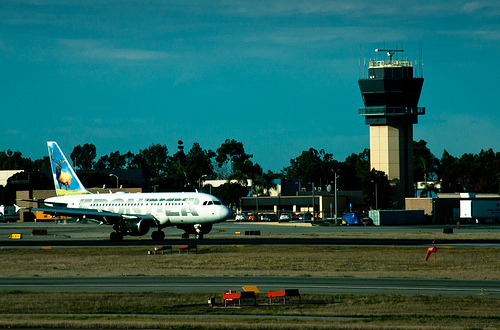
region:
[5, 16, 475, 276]
airport with an airplane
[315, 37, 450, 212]
airplane tower is overhead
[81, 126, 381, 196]
tree line is green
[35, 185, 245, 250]
landing gear is down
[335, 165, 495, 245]
airport tower base in background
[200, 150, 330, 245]
runway buildings behind the scene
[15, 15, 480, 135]
cloudless sky in the background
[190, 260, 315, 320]
runway objects on the ground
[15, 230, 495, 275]
grassy ground beneath the plane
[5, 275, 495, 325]
grassy area for airport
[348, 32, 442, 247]
air traffic controller tower at airport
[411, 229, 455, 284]
orange reflective wind sock at airport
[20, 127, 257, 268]
large jetliner at airport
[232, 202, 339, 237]
cars parked in parking lot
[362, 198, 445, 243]
storage building at airport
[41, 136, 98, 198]
elk painted on tail wing of airport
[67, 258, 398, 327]
asphalt runway at airport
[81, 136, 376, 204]
trees with green leaves at a distanse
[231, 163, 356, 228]
building on airport property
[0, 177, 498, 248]
airplane going down run way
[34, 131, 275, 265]
white plane with design on tail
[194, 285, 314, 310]
several colored tables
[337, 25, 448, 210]
large air traffic control tower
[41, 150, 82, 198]
blue and yellow on airplane tail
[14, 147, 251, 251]
airplane on tar mac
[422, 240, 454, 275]
something red in median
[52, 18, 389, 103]
light whispy clouds in sky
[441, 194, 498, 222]
white box truck in photograph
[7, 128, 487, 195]
row of trees in photograph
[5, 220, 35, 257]
something yellow on runway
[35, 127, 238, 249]
Passenger plane on the runway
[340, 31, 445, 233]
Airport control tower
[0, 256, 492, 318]
Empty runway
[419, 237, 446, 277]
Small orange windsock next to runway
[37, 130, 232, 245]
Frontier Airlines plane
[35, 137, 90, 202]
Elk painted on the tail of a plane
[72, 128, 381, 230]
Trees near the airport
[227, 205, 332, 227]
A row of parked cars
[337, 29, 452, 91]
Antennas on the roof of a control tower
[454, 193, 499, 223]
A shipping container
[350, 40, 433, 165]
Airiport control tower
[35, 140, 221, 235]
Airplane on tarmac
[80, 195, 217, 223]
Name FRONTIER on side of plane.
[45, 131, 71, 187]
Picture of deer on tail of aircraft.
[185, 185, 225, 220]
Cockpit of aircraft on tarmac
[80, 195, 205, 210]
Side windows in airplane on tarmac.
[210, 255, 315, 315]
Markers use by airports.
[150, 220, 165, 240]
Airplane landing gear.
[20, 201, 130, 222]
Blue wing of Frontier airplane.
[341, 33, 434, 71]
Beacon mounted on top of control tower.